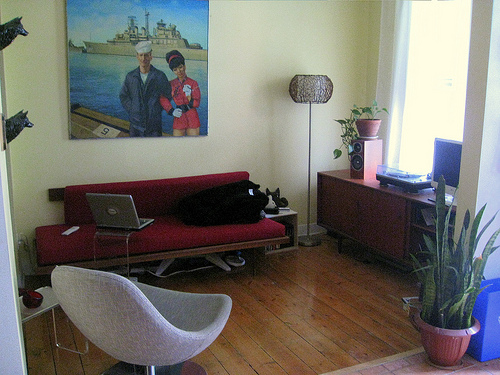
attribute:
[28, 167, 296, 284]
couch — red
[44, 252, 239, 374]
chair — here, gray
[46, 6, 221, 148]
painting — here, large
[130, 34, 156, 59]
hat — white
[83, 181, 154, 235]
laptop — here, gray, silver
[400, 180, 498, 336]
plant — tall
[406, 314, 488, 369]
brown container — here, reddish brown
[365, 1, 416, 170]
curtains — drawn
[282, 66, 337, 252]
lamp — tall, here, brown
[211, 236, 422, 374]
floors — wood, here, brown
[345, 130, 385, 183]
speaker — here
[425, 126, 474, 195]
television — small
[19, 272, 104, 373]
table — small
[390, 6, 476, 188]
window — large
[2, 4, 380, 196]
wall — white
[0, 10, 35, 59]
statie — hanging